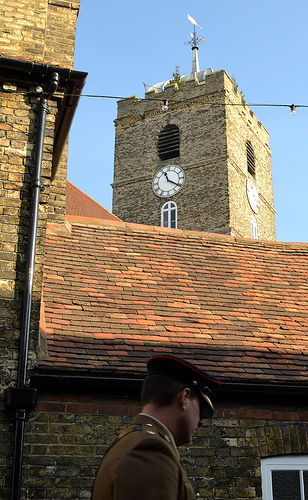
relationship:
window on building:
[121, 63, 304, 223] [118, 71, 234, 235]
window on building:
[248, 209, 259, 239] [110, 69, 277, 241]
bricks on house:
[0, 395, 307, 496] [0, 0, 306, 499]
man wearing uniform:
[88, 352, 222, 499] [91, 412, 200, 497]